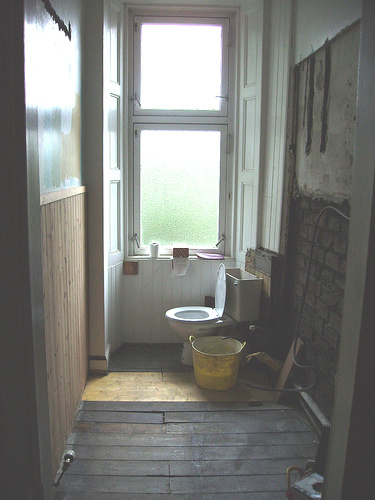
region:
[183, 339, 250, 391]
yellow bucket on floor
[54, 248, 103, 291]
wood on the wall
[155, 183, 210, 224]
window in the bathroom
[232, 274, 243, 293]
flusher on the toilet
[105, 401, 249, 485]
wood planks on floor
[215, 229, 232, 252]
knob on the window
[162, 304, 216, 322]
seat of the toilet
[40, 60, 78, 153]
top part of wall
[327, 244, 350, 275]
brick area on wall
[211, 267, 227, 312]
lid on the toilet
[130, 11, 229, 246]
Two bathroom windows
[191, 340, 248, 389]
A dirty yellow bucket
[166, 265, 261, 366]
A dirty white toilet stool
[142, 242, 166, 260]
A roll of toilet paper on the window sill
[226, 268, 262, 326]
A toilet tank without a lid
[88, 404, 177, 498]
An old wooden bathroom floor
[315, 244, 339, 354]
An old brick wall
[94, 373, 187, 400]
A replaced part of the wooden floor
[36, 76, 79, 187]
A bathroom wall with paint samples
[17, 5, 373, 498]
A bathroom being remodeled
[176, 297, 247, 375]
White toilet in bathroom.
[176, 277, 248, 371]
Toilet lid is up and open.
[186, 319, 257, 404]
yellow bucket next to toilet.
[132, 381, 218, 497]
Floor is made from wood planks.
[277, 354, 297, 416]
Piece of wood leaning against wall.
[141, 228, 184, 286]
Toilet paper roll on ledge.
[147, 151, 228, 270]
Large window in bathroom.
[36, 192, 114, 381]
Wall is wood on bottom half.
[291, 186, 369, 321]
Bricks halfway up the wall.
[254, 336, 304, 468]
Cord hanging down near wall.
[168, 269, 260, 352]
One toilet is seen.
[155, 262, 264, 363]
Toilet is white color.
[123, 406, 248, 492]
Floor is brown color.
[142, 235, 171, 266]
tissue roll is in window.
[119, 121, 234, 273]
One window in toilet.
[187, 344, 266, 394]
Bucket is yellow color.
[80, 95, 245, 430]
Sunlight is passing through window.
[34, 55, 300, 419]
Day time picture.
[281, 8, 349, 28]
Walls are white color.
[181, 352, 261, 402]
Bucket is in floor.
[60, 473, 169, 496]
a wooden timber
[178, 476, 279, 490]
a wooden timber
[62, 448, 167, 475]
a wooden timber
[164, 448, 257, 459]
a wooden timber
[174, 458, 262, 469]
a wooden timber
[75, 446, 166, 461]
a wooden timber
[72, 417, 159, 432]
a wooden timber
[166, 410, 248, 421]
a wooden timber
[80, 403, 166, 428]
a wooden timber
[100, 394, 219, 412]
a wooden timber